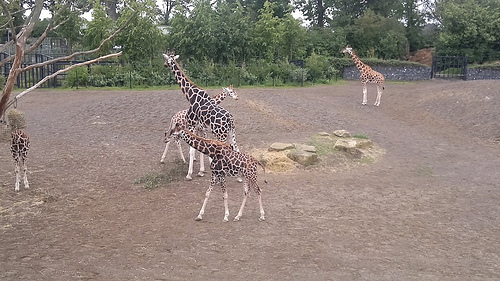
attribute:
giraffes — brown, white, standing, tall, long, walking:
[156, 51, 267, 221]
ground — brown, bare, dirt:
[2, 78, 499, 279]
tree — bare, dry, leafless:
[0, 0, 134, 124]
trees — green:
[62, 0, 340, 86]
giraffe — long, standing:
[340, 44, 386, 107]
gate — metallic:
[7, 52, 60, 89]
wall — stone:
[344, 60, 432, 82]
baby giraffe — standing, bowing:
[9, 129, 31, 193]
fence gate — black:
[431, 52, 469, 80]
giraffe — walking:
[162, 123, 267, 222]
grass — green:
[47, 84, 333, 89]